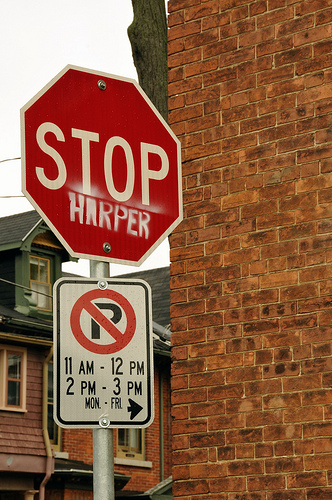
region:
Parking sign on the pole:
[44, 270, 159, 429]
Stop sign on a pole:
[9, 58, 185, 270]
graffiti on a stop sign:
[62, 186, 155, 251]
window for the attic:
[29, 252, 51, 302]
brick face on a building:
[219, 106, 320, 393]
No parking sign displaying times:
[53, 273, 170, 433]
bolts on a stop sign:
[98, 242, 112, 251]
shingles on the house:
[3, 420, 44, 451]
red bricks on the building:
[219, 355, 288, 442]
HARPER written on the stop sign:
[61, 184, 165, 242]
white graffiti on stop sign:
[66, 197, 162, 240]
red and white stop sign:
[18, 65, 201, 272]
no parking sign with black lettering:
[42, 271, 171, 432]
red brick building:
[178, 80, 316, 491]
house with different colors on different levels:
[3, 208, 81, 493]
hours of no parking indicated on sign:
[62, 349, 148, 419]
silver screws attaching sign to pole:
[94, 414, 113, 435]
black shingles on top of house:
[2, 204, 38, 246]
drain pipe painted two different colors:
[33, 343, 58, 499]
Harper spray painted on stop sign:
[63, 192, 158, 234]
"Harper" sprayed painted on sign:
[63, 192, 150, 241]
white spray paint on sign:
[68, 192, 153, 255]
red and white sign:
[10, 59, 189, 270]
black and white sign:
[42, 272, 155, 432]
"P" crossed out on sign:
[66, 284, 147, 358]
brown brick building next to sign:
[160, 0, 331, 498]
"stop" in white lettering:
[36, 118, 171, 218]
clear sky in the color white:
[0, 0, 135, 75]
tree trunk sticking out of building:
[123, 0, 170, 103]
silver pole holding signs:
[89, 427, 116, 497]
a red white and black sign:
[51, 268, 188, 439]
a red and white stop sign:
[19, 55, 206, 260]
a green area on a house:
[0, 205, 69, 320]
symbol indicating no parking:
[63, 285, 139, 356]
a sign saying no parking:
[53, 276, 156, 439]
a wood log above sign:
[116, 0, 194, 136]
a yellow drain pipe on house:
[33, 346, 58, 474]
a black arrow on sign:
[119, 393, 149, 427]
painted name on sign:
[65, 192, 165, 248]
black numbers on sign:
[62, 350, 138, 406]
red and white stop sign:
[18, 61, 184, 270]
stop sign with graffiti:
[17, 62, 185, 268]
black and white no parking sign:
[50, 274, 156, 430]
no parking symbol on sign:
[68, 286, 137, 356]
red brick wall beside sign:
[163, 1, 330, 498]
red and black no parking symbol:
[69, 285, 139, 356]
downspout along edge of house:
[37, 347, 55, 498]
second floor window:
[0, 343, 28, 414]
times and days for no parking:
[61, 351, 147, 423]